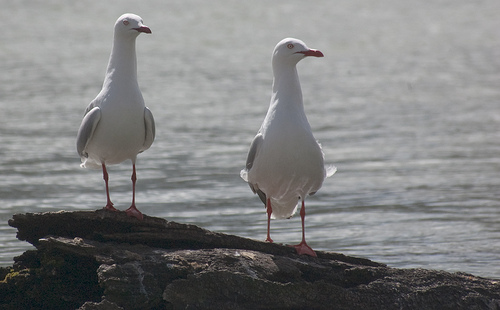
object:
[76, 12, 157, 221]
two birds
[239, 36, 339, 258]
bird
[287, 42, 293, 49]
eye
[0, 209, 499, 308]
rocks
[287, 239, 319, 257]
feet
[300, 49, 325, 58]
beak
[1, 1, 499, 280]
water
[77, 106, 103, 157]
wing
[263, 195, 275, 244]
legs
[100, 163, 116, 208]
legs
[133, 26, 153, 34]
beak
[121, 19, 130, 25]
eye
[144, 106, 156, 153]
wings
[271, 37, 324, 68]
head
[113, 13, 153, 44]
head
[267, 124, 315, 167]
chest